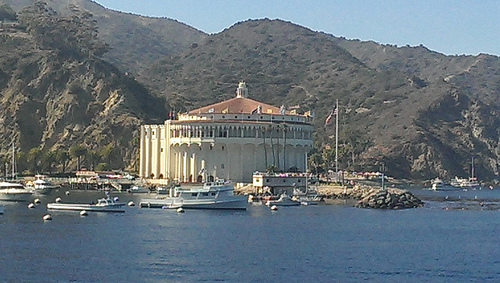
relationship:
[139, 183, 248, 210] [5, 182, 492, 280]
boat in water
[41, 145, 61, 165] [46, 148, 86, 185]
leaves on tree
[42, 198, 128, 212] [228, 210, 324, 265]
boat in water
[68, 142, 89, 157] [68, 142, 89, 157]
leaves on leaves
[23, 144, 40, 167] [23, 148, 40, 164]
leaves on leaves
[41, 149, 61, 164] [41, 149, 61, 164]
leaves on leaves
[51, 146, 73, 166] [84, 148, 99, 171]
leaves on tree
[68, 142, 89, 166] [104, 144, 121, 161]
leaves on leaves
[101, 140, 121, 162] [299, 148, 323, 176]
leaves on tree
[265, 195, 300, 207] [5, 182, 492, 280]
boat in water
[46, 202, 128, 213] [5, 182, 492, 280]
boat in water